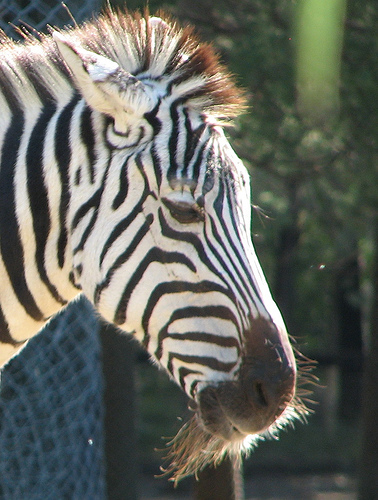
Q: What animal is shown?
A: Zebra.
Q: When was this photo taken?
A: During the daytime.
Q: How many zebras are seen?
A: One.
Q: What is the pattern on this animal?
A: Striped.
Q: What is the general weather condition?
A: Sunny.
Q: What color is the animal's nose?
A: Black.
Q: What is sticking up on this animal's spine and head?
A: Mane.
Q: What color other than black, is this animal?
A: White.